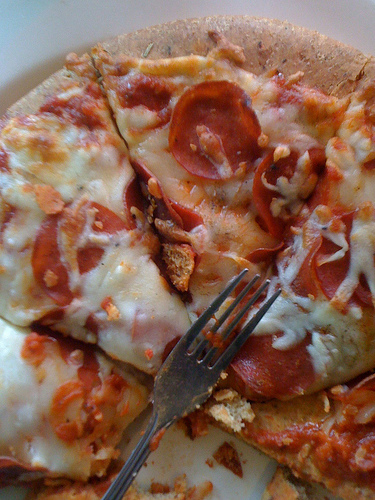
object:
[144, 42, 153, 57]
seasoning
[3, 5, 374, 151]
bread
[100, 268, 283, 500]
fork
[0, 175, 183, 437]
melted cheese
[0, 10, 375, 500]
pizza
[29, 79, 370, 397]
meat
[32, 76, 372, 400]
pepperoni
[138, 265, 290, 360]
spoon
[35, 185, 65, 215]
crumb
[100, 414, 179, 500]
handle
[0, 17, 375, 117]
crust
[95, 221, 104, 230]
crumb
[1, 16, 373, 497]
crust crumb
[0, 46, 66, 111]
light brown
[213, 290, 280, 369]
part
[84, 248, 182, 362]
cheese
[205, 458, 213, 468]
crunch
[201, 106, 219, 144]
tomato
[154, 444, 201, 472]
plate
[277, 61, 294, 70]
part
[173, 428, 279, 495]
surface